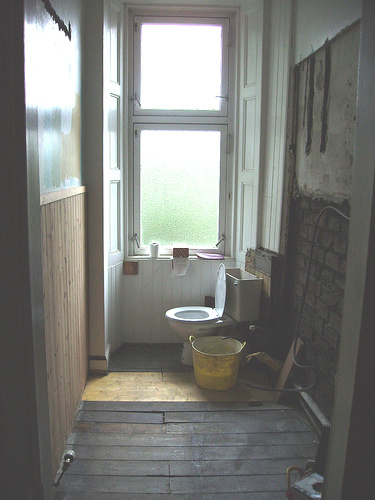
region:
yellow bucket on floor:
[183, 339, 250, 391]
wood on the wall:
[54, 248, 103, 291]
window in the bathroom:
[155, 183, 210, 224]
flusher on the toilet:
[232, 274, 243, 293]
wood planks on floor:
[105, 401, 249, 485]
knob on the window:
[215, 229, 232, 252]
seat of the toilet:
[162, 304, 216, 322]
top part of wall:
[40, 60, 78, 153]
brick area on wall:
[327, 244, 350, 275]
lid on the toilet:
[211, 267, 227, 312]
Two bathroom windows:
[130, 11, 229, 246]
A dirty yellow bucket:
[191, 340, 248, 389]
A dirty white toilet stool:
[166, 265, 261, 366]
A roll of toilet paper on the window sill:
[142, 242, 166, 260]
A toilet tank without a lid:
[226, 268, 262, 326]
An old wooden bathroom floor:
[88, 404, 177, 498]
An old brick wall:
[315, 244, 339, 354]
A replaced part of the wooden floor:
[94, 373, 187, 400]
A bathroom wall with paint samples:
[36, 76, 79, 187]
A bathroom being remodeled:
[17, 5, 373, 498]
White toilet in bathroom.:
[176, 297, 247, 375]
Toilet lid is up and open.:
[176, 277, 248, 371]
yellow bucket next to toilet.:
[186, 319, 257, 404]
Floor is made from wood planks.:
[132, 381, 218, 497]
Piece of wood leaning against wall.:
[277, 354, 297, 416]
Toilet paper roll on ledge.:
[141, 228, 184, 286]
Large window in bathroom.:
[147, 151, 228, 270]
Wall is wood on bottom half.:
[36, 192, 114, 381]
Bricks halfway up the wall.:
[291, 186, 369, 321]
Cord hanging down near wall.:
[254, 336, 304, 468]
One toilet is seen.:
[168, 269, 260, 352]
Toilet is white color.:
[155, 262, 264, 363]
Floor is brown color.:
[123, 406, 248, 492]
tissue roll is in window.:
[142, 235, 171, 266]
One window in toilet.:
[119, 121, 234, 273]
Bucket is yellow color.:
[187, 344, 266, 394]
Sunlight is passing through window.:
[80, 95, 245, 430]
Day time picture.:
[34, 55, 300, 419]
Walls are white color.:
[281, 8, 349, 28]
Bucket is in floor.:
[181, 352, 261, 402]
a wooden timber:
[60, 473, 169, 496]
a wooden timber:
[178, 476, 279, 490]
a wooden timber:
[62, 448, 167, 475]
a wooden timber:
[164, 448, 257, 459]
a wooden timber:
[174, 458, 262, 469]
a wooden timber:
[75, 446, 166, 461]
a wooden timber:
[72, 417, 159, 432]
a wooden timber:
[166, 410, 248, 421]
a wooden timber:
[80, 403, 166, 428]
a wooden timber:
[100, 394, 219, 412]